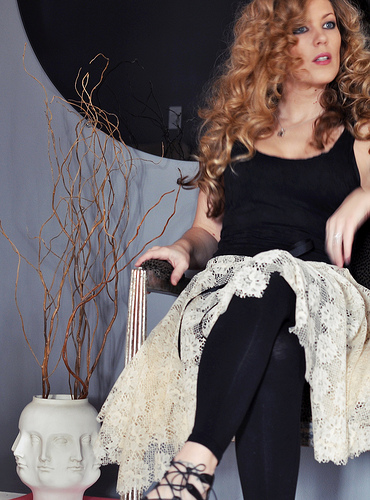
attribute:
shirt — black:
[211, 126, 360, 267]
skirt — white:
[133, 243, 368, 453]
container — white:
[13, 393, 110, 492]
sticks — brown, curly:
[2, 41, 181, 399]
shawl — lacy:
[94, 246, 369, 499]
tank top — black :
[200, 103, 364, 267]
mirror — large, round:
[17, 0, 194, 161]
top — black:
[140, 2, 360, 496]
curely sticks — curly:
[27, 76, 108, 395]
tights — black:
[188, 265, 315, 498]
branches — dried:
[24, 44, 200, 405]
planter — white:
[10, 393, 104, 498]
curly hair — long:
[189, 2, 369, 217]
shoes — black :
[147, 461, 218, 497]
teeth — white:
[317, 55, 329, 63]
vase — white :
[7, 391, 113, 499]